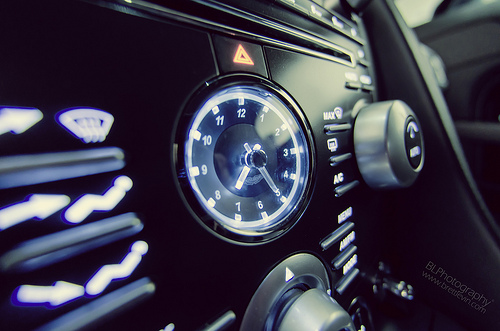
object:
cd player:
[0, 0, 425, 331]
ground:
[396, 152, 454, 191]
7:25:
[234, 142, 287, 221]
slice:
[0, 188, 70, 232]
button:
[284, 266, 294, 281]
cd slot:
[116, 0, 359, 65]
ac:
[333, 180, 360, 198]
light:
[232, 43, 254, 64]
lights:
[64, 175, 134, 224]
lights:
[85, 241, 149, 295]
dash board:
[0, 0, 382, 330]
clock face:
[184, 86, 310, 237]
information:
[422, 261, 491, 314]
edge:
[381, 117, 401, 182]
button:
[405, 116, 423, 170]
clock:
[171, 72, 315, 246]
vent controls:
[0, 106, 149, 331]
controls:
[238, 253, 354, 331]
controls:
[353, 100, 425, 188]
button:
[0, 148, 125, 188]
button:
[325, 123, 352, 132]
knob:
[276, 288, 356, 331]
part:
[235, 144, 283, 221]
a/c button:
[0, 105, 164, 330]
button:
[208, 33, 270, 79]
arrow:
[0, 192, 70, 229]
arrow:
[0, 105, 43, 135]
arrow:
[17, 280, 85, 306]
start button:
[59, 108, 115, 143]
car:
[0, 0, 499, 331]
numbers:
[216, 116, 225, 126]